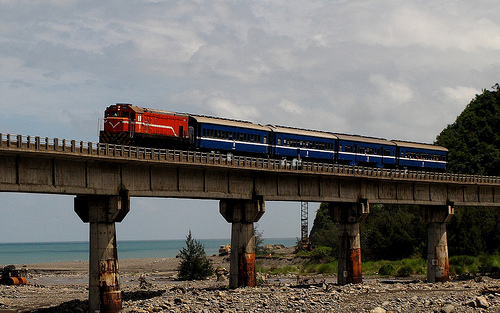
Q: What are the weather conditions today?
A: It is cloudy.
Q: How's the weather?
A: It is cloudy.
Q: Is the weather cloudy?
A: Yes, it is cloudy.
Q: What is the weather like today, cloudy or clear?
A: It is cloudy.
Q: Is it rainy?
A: No, it is cloudy.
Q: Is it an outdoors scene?
A: Yes, it is outdoors.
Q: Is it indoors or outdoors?
A: It is outdoors.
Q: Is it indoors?
A: No, it is outdoors.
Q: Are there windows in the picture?
A: Yes, there are windows.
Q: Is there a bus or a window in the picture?
A: Yes, there are windows.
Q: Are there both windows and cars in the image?
A: Yes, there are both windows and a car.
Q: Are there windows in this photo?
A: Yes, there are windows.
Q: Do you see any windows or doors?
A: Yes, there are windows.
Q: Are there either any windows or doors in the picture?
A: Yes, there are windows.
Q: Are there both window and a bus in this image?
A: No, there are windows but no buses.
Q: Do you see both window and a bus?
A: No, there are windows but no buses.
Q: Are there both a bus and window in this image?
A: No, there are windows but no buses.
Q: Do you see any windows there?
A: Yes, there are windows.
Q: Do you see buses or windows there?
A: Yes, there are windows.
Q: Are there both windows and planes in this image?
A: No, there are windows but no airplanes.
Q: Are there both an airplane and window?
A: No, there are windows but no airplanes.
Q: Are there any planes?
A: No, there are no planes.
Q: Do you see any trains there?
A: Yes, there is a train.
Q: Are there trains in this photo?
A: Yes, there is a train.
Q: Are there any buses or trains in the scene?
A: Yes, there is a train.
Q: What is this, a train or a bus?
A: This is a train.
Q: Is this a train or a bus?
A: This is a train.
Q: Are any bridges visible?
A: Yes, there is a bridge.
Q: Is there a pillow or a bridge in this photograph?
A: Yes, there is a bridge.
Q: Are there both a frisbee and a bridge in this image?
A: No, there is a bridge but no frisbees.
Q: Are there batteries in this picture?
A: No, there are no batteries.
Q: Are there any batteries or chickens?
A: No, there are no batteries or chickens.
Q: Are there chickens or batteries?
A: No, there are no batteries or chickens.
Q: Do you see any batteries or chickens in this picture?
A: No, there are no batteries or chickens.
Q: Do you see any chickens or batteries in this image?
A: No, there are no batteries or chickens.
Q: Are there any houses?
A: No, there are no houses.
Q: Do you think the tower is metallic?
A: Yes, the tower is metallic.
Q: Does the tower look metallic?
A: Yes, the tower is metallic.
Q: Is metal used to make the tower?
A: Yes, the tower is made of metal.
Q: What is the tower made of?
A: The tower is made of metal.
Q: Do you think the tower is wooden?
A: No, the tower is metallic.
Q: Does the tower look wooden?
A: No, the tower is metallic.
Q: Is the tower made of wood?
A: No, the tower is made of metal.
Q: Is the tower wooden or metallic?
A: The tower is metallic.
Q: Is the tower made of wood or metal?
A: The tower is made of metal.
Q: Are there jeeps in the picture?
A: No, there are no jeeps.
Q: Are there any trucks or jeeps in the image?
A: No, there are no jeeps or trucks.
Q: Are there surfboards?
A: No, there are no surfboards.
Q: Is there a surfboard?
A: No, there are no surfboards.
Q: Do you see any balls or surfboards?
A: No, there are no surfboards or balls.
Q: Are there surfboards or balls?
A: No, there are no surfboards or balls.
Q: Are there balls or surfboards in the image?
A: No, there are no surfboards or balls.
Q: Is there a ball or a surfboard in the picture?
A: No, there are no surfboards or balls.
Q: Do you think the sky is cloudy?
A: Yes, the sky is cloudy.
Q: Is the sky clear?
A: No, the sky is cloudy.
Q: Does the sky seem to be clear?
A: No, the sky is cloudy.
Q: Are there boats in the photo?
A: No, there are no boats.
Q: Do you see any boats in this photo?
A: No, there are no boats.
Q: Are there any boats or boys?
A: No, there are no boats or boys.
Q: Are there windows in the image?
A: Yes, there are windows.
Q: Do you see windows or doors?
A: Yes, there are windows.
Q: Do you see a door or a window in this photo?
A: Yes, there are windows.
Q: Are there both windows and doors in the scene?
A: Yes, there are both windows and a door.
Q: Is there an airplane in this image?
A: No, there are no airplanes.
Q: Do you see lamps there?
A: No, there are no lamps.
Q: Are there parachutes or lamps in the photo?
A: No, there are no lamps or parachutes.